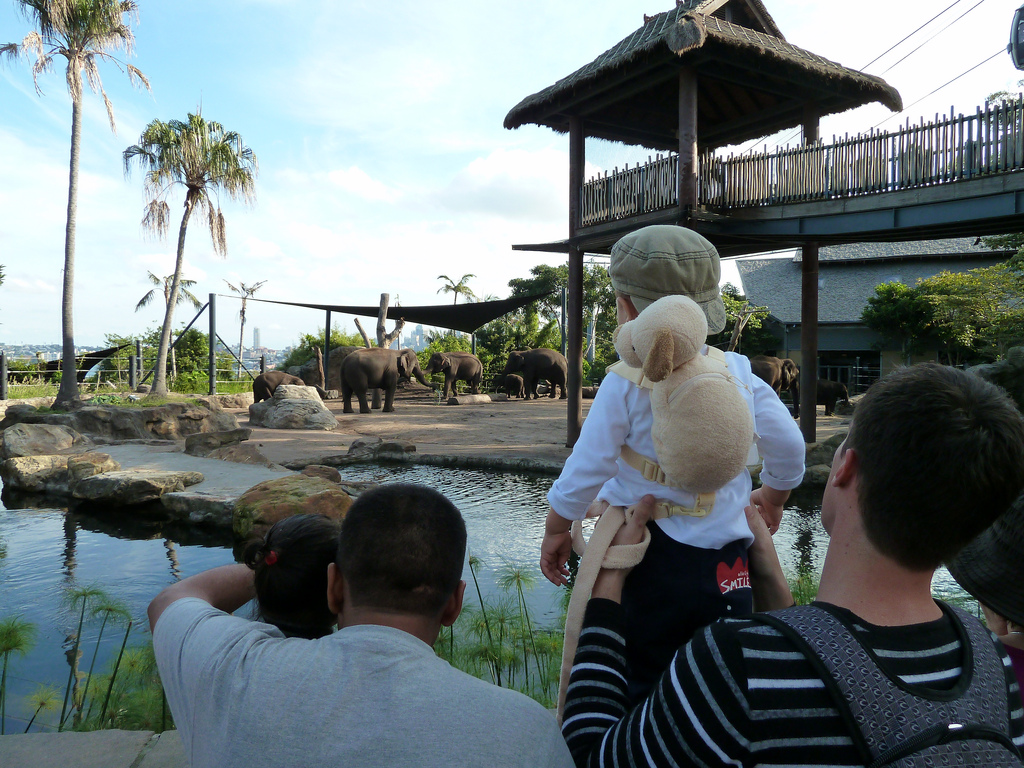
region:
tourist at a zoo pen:
[178, 456, 602, 733]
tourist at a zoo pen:
[230, 490, 351, 618]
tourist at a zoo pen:
[612, 221, 737, 553]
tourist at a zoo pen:
[799, 364, 993, 763]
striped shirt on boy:
[567, 560, 1019, 753]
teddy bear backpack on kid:
[621, 317, 746, 524]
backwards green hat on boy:
[644, 240, 737, 342]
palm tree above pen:
[148, 99, 243, 248]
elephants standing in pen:
[311, 332, 577, 394]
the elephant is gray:
[331, 327, 437, 419]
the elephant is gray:
[243, 362, 314, 414]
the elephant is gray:
[423, 344, 493, 411]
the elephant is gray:
[495, 336, 576, 403]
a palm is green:
[109, 90, 271, 410]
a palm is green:
[19, 3, 138, 427]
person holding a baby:
[520, 210, 1015, 765]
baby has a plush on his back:
[511, 197, 821, 562]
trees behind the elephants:
[256, 283, 585, 436]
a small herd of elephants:
[194, 294, 607, 428]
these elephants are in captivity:
[197, 275, 591, 454]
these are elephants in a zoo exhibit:
[232, 278, 612, 453]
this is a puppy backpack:
[589, 268, 767, 509]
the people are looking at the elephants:
[81, 142, 1015, 766]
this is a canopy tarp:
[251, 263, 594, 340]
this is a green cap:
[604, 203, 747, 356]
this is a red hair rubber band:
[251, 538, 289, 580]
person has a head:
[614, 232, 726, 332]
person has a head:
[818, 366, 1022, 566]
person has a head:
[254, 520, 349, 637]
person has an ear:
[616, 293, 630, 323]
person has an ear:
[441, 577, 471, 632]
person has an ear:
[324, 562, 345, 620]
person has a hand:
[542, 533, 577, 592]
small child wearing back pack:
[535, 228, 810, 596]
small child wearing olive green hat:
[539, 222, 808, 590]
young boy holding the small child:
[558, 361, 1020, 758]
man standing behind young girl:
[147, 484, 618, 759]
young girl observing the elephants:
[244, 524, 352, 630]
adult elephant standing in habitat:
[342, 347, 434, 420]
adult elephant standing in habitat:
[429, 354, 488, 394]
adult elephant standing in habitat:
[507, 347, 568, 396]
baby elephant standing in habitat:
[489, 375, 524, 398]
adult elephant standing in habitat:
[251, 369, 303, 404]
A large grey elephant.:
[332, 343, 424, 426]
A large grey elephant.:
[247, 367, 286, 391]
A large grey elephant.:
[416, 340, 496, 388]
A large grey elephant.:
[489, 374, 531, 403]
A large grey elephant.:
[505, 352, 567, 390]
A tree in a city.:
[145, 272, 193, 387]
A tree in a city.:
[227, 275, 254, 361]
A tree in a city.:
[138, 95, 244, 384]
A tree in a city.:
[19, 8, 149, 411]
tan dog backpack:
[602, 289, 764, 515]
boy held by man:
[565, 213, 793, 575]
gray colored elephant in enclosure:
[332, 331, 428, 429]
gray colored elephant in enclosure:
[426, 346, 478, 410]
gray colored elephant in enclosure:
[495, 336, 569, 406]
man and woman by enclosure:
[154, 466, 540, 765]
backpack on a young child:
[618, 290, 754, 509]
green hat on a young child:
[609, 225, 742, 346]